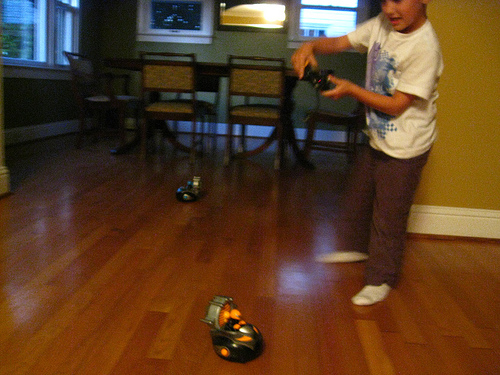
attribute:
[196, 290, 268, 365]
race car — remote controlled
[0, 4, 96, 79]
window — white 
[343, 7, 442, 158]
t-shirt — white 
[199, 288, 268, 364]
car — orange, black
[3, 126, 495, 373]
hardwood floor — tan 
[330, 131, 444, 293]
pants — brown 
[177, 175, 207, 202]
car — blue, silver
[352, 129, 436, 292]
pants — brown 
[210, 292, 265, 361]
toy — yellow , black 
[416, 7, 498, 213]
wall — tan 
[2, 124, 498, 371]
floor — tan, hardwood, clean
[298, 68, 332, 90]
remote — black 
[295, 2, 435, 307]
boy — little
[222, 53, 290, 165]
chair — brown 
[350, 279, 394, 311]
socks — white 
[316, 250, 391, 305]
socks — white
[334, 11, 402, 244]
child — small 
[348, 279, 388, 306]
sock — white